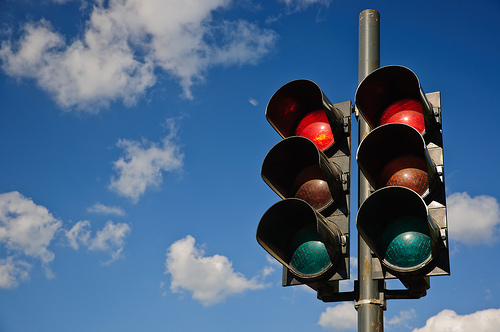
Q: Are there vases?
A: No, there are no vases.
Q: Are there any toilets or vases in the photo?
A: No, there are no vases or toilets.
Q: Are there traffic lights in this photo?
A: Yes, there is a traffic light.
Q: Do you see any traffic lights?
A: Yes, there is a traffic light.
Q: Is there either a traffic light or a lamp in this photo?
A: Yes, there is a traffic light.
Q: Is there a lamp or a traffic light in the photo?
A: Yes, there is a traffic light.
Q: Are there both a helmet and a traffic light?
A: No, there is a traffic light but no helmets.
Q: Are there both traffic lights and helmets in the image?
A: No, there is a traffic light but no helmets.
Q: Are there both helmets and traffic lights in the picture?
A: No, there is a traffic light but no helmets.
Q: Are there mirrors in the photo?
A: No, there are no mirrors.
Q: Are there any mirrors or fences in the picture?
A: No, there are no mirrors or fences.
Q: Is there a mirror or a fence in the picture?
A: No, there are no mirrors or fences.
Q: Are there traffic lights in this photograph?
A: Yes, there is a traffic light.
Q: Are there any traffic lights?
A: Yes, there is a traffic light.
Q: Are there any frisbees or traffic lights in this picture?
A: Yes, there is a traffic light.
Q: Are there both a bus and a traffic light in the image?
A: No, there is a traffic light but no buses.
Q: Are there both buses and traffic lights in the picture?
A: No, there is a traffic light but no buses.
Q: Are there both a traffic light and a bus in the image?
A: No, there is a traffic light but no buses.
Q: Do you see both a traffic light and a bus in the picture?
A: No, there is a traffic light but no buses.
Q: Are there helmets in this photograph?
A: No, there are no helmets.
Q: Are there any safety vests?
A: No, there are no safety vests.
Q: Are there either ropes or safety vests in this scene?
A: No, there are no safety vests or ropes.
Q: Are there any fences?
A: No, there are no fences.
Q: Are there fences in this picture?
A: No, there are no fences.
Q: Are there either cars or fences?
A: No, there are no fences or cars.